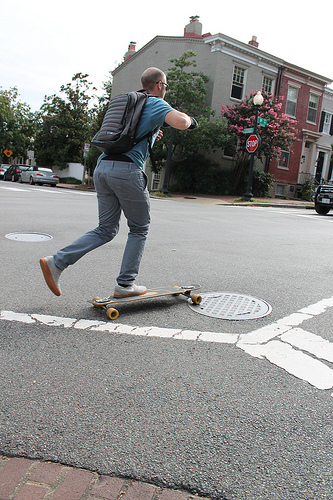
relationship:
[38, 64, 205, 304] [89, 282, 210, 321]
man on skate board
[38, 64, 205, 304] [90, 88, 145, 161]
man carrying back pack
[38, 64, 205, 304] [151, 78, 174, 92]
man wears glasses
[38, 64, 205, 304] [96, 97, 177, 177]
man wears shirt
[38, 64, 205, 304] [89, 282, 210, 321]
man has skate board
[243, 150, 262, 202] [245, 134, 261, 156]
pole connects sign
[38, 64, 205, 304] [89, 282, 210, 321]
man riding skate board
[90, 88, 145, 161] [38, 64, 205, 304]
back pack on man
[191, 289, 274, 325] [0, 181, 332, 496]
cover in street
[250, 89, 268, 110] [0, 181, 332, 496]
light by street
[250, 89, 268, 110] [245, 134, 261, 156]
light near sign